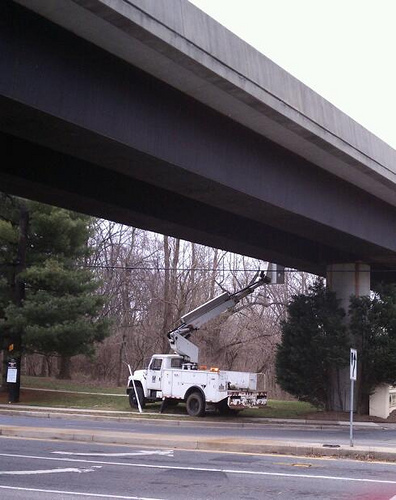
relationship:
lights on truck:
[186, 346, 240, 388] [126, 266, 295, 410]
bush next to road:
[264, 287, 395, 416] [0, 400, 395, 497]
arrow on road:
[0, 463, 103, 476] [0, 400, 395, 497]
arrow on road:
[51, 447, 175, 461] [0, 400, 395, 497]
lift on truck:
[165, 276, 265, 363] [126, 352, 268, 417]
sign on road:
[348, 346, 358, 381] [0, 400, 395, 497]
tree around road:
[272, 276, 344, 411] [0, 400, 395, 497]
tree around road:
[0, 196, 115, 401] [0, 400, 395, 497]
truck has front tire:
[126, 271, 270, 414] [128, 387, 146, 407]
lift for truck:
[165, 276, 265, 363] [125, 346, 268, 421]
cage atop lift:
[256, 259, 285, 285] [166, 283, 265, 363]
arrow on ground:
[48, 447, 175, 461] [11, 407, 394, 490]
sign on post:
[346, 346, 358, 383] [347, 377, 354, 448]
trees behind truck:
[100, 244, 151, 369] [125, 352, 256, 405]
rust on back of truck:
[226, 390, 272, 411] [125, 258, 287, 415]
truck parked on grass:
[126, 271, 270, 414] [26, 386, 128, 404]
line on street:
[101, 454, 324, 495] [0, 401, 394, 498]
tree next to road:
[1, 196, 109, 381] [0, 400, 395, 497]